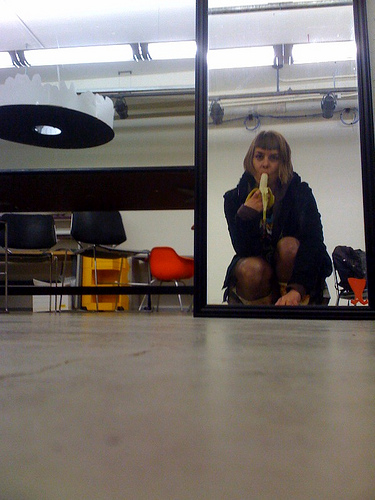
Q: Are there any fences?
A: No, there are no fences.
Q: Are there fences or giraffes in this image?
A: No, there are no fences or giraffes.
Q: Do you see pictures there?
A: No, there are no pictures.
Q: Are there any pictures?
A: No, there are no pictures.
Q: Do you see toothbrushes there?
A: No, there are no toothbrushes.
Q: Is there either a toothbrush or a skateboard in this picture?
A: No, there are no toothbrushes or skateboards.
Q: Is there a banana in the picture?
A: Yes, there is a banana.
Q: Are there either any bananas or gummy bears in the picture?
A: Yes, there is a banana.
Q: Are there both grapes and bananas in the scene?
A: No, there is a banana but no grapes.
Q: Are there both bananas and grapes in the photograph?
A: No, there is a banana but no grapes.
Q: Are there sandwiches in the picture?
A: No, there are no sandwiches.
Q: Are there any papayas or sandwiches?
A: No, there are no sandwiches or papayas.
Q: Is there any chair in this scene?
A: Yes, there is a chair.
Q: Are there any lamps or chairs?
A: Yes, there is a chair.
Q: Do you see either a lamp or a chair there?
A: Yes, there is a chair.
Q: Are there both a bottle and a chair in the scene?
A: No, there is a chair but no bottles.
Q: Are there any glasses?
A: No, there are no glasses.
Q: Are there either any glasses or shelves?
A: No, there are no glasses or shelves.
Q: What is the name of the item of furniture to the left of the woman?
A: The piece of furniture is a chair.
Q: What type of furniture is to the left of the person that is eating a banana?
A: The piece of furniture is a chair.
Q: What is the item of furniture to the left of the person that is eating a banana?
A: The piece of furniture is a chair.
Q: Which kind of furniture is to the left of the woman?
A: The piece of furniture is a chair.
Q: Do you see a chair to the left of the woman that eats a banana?
A: Yes, there is a chair to the left of the woman.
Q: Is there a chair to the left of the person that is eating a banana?
A: Yes, there is a chair to the left of the woman.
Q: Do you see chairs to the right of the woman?
A: No, the chair is to the left of the woman.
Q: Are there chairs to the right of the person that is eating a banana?
A: No, the chair is to the left of the woman.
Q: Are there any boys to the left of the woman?
A: No, there is a chair to the left of the woman.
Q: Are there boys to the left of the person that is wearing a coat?
A: No, there is a chair to the left of the woman.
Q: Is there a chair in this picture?
A: Yes, there is a chair.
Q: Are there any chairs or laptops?
A: Yes, there is a chair.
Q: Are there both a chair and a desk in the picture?
A: No, there is a chair but no desks.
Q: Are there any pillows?
A: No, there are no pillows.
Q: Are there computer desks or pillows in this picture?
A: No, there are no pillows or computer desks.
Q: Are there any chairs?
A: Yes, there is a chair.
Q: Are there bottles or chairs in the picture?
A: Yes, there is a chair.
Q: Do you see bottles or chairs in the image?
A: Yes, there is a chair.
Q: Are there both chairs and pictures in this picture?
A: No, there is a chair but no pictures.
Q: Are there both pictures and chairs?
A: No, there is a chair but no pictures.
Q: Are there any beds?
A: No, there are no beds.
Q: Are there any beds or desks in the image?
A: No, there are no beds or desks.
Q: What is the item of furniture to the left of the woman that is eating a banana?
A: The piece of furniture is a chair.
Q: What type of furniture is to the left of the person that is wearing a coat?
A: The piece of furniture is a chair.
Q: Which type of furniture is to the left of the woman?
A: The piece of furniture is a chair.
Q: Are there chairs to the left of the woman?
A: Yes, there is a chair to the left of the woman.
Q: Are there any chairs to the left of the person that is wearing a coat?
A: Yes, there is a chair to the left of the woman.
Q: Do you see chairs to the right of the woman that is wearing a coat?
A: No, the chair is to the left of the woman.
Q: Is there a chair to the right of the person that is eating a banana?
A: No, the chair is to the left of the woman.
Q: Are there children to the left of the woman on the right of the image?
A: No, there is a chair to the left of the woman.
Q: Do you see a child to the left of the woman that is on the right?
A: No, there is a chair to the left of the woman.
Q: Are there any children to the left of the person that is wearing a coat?
A: No, there is a chair to the left of the woman.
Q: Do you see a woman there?
A: Yes, there is a woman.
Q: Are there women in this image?
A: Yes, there is a woman.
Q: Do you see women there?
A: Yes, there is a woman.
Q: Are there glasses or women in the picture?
A: Yes, there is a woman.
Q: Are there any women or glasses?
A: Yes, there is a woman.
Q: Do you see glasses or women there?
A: Yes, there is a woman.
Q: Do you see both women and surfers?
A: No, there is a woman but no surfers.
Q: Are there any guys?
A: No, there are no guys.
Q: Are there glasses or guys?
A: No, there are no guys or glasses.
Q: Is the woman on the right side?
A: Yes, the woman is on the right of the image.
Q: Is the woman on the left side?
A: No, the woman is on the right of the image.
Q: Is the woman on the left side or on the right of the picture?
A: The woman is on the right of the image.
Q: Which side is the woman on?
A: The woman is on the right of the image.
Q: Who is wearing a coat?
A: The woman is wearing a coat.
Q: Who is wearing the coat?
A: The woman is wearing a coat.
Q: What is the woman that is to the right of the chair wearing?
A: The woman is wearing a coat.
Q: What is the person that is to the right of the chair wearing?
A: The woman is wearing a coat.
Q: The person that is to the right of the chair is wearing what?
A: The woman is wearing a coat.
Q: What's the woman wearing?
A: The woman is wearing a coat.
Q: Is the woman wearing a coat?
A: Yes, the woman is wearing a coat.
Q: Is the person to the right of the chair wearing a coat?
A: Yes, the woman is wearing a coat.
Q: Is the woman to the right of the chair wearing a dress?
A: No, the woman is wearing a coat.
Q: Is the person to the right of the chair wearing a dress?
A: No, the woman is wearing a coat.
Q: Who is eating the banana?
A: The woman is eating the banana.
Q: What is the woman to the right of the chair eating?
A: The woman is eating a banana.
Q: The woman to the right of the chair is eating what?
A: The woman is eating a banana.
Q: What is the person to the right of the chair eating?
A: The woman is eating a banana.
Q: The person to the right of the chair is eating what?
A: The woman is eating a banana.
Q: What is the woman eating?
A: The woman is eating a banana.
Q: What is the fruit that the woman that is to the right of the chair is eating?
A: The fruit is a banana.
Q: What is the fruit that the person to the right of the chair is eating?
A: The fruit is a banana.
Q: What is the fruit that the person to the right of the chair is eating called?
A: The fruit is a banana.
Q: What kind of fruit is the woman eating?
A: The woman is eating a banana.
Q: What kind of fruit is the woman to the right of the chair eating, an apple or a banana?
A: The woman is eating a banana.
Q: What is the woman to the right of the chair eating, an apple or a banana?
A: The woman is eating a banana.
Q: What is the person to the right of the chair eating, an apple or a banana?
A: The woman is eating a banana.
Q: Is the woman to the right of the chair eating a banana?
A: Yes, the woman is eating a banana.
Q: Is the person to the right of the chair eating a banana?
A: Yes, the woman is eating a banana.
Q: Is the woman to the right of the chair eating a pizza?
A: No, the woman is eating a banana.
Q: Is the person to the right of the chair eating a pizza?
A: No, the woman is eating a banana.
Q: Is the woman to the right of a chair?
A: Yes, the woman is to the right of a chair.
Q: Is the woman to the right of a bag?
A: No, the woman is to the right of a chair.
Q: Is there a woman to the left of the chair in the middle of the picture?
A: No, the woman is to the right of the chair.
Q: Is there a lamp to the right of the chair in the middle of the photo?
A: No, there is a woman to the right of the chair.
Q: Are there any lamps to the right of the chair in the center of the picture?
A: No, there is a woman to the right of the chair.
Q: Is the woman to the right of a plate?
A: No, the woman is to the right of the chair.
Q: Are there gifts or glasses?
A: No, there are no glasses or gifts.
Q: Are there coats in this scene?
A: Yes, there is a coat.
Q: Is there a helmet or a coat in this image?
A: Yes, there is a coat.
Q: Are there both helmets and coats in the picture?
A: No, there is a coat but no helmets.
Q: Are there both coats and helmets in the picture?
A: No, there is a coat but no helmets.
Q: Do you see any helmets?
A: No, there are no helmets.